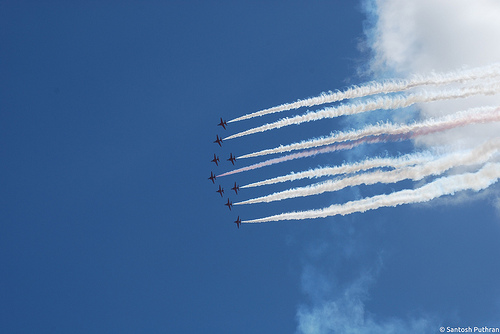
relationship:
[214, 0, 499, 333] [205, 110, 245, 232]
tail smoke from jets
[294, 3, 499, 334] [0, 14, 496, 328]
cloud in sky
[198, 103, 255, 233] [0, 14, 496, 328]
airplanes in sky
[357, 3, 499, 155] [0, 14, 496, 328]
cloud in sky